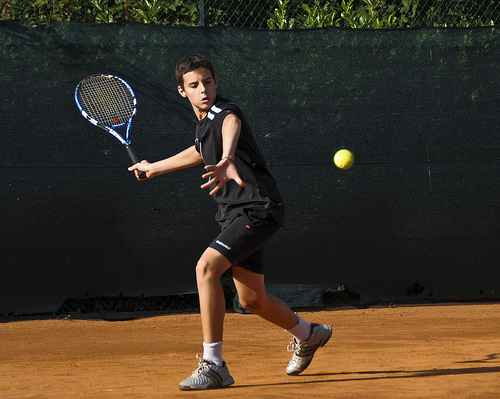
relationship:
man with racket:
[103, 46, 407, 352] [54, 66, 162, 172]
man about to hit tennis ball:
[126, 56, 331, 391] [324, 145, 357, 171]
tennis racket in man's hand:
[68, 71, 151, 177] [123, 153, 160, 187]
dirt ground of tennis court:
[16, 330, 162, 388] [9, 311, 496, 392]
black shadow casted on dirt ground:
[225, 353, 497, 385] [0, 304, 497, 399]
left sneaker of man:
[176, 355, 234, 387] [126, 56, 331, 391]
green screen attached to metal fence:
[297, 51, 497, 132] [3, 2, 493, 313]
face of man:
[185, 77, 215, 109] [126, 56, 331, 391]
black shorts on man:
[179, 210, 296, 286] [126, 56, 331, 391]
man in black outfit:
[126, 56, 331, 391] [187, 98, 294, 278]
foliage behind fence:
[4, 0, 490, 23] [22, 0, 496, 310]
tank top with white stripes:
[183, 100, 283, 210] [202, 93, 228, 124]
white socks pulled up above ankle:
[201, 343, 225, 359] [205, 341, 220, 353]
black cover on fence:
[1, 32, 495, 316] [0, 19, 496, 314]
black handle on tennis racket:
[116, 137, 146, 185] [68, 71, 151, 177]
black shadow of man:
[225, 350, 497, 388] [126, 56, 331, 391]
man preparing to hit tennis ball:
[126, 56, 331, 391] [329, 148, 356, 171]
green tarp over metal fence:
[0, 30, 493, 315] [3, 2, 493, 313]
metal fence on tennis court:
[3, 2, 493, 313] [3, 319, 498, 392]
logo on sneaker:
[202, 364, 224, 382] [177, 351, 239, 391]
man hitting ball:
[126, 56, 331, 391] [328, 141, 361, 174]